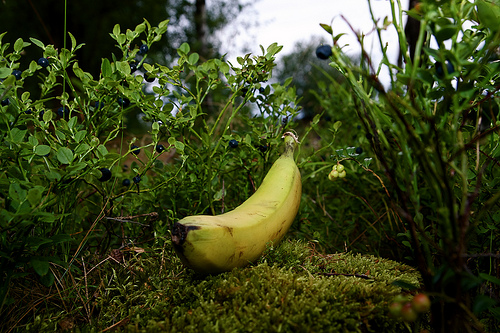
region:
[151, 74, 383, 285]
a banana in the grass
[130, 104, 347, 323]
a yellow banana on the grass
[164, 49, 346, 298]
a banana outside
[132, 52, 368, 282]
a ripe banana on the grass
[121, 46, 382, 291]
a ripe yellow banana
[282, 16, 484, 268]
tall green grass outside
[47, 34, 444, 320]
banana surround by tall grass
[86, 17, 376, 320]
banana surround by green grass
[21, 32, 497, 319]
green grass with a banana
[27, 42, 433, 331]
green grass with a fruit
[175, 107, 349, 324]
the banana is yellow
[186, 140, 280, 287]
the banana is yellow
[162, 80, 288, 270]
the banana is yellow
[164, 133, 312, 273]
Yellow and green banana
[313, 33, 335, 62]
Small blueberry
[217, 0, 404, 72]
Sky in the background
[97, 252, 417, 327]
Green moss underneath the banana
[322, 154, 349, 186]
Small white berries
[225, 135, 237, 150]
Very small blueberry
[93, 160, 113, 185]
Larger blueberry on the bush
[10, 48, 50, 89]
Two blueberries on the bush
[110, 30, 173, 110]
Four blueberries on the bush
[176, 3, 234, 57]
Tree in the background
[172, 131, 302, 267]
The banana is yellow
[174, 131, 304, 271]
The banana is alone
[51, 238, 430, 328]
The bushes are green holding the banana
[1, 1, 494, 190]
Blueberries hanging in bushes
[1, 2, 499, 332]
green leaves and vines bearing fruit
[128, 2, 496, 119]
sky is white and out of focus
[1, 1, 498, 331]
Scene is out door shot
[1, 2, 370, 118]
Trees blurred in background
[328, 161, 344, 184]
small cluster of green berries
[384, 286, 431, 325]
fruit on bottom is green and red